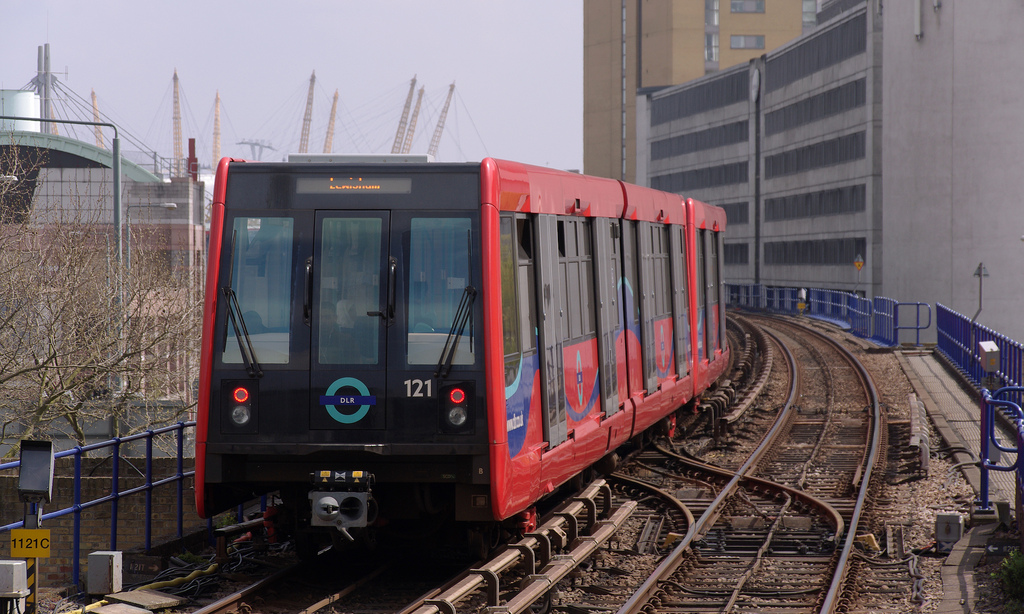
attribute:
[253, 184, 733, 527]
train — black, red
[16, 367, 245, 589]
fence — blue, metal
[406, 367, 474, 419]
light — red, off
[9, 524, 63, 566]
sign — yellow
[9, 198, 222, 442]
tree — bare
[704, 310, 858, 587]
tracks — rusty, brown, curved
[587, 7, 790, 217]
building — tan, grey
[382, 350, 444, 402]
number — white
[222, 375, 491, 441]
lights — on left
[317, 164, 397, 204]
destination — changeable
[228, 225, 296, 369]
window — large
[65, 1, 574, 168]
sky — blue, overcast